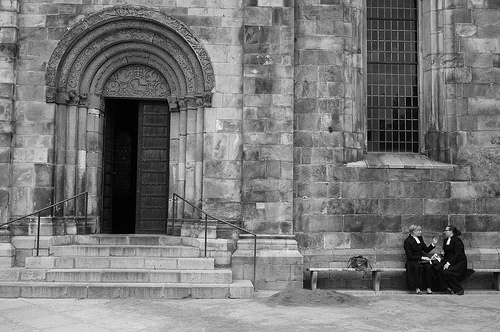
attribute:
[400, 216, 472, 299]
people — seated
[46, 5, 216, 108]
archway — STONE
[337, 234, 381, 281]
bird — SMALL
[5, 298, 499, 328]
road — CONCRETE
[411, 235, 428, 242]
collar — white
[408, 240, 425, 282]
dress — long, black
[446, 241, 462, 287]
dress — long, black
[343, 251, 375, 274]
purse — black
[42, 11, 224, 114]
arch way — large, curved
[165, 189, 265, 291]
railing — black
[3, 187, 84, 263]
railing — black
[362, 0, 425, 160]
window — GLASS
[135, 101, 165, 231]
door — open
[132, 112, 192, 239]
door — closed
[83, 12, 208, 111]
archway — carved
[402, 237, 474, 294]
costumes — black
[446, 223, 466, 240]
hair — black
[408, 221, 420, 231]
hair cut — short, blond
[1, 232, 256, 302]
steps — large, stone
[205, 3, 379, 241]
wall — white 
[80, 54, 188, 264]
door — OPEN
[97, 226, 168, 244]
step — at door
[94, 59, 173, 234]
door — dome shaped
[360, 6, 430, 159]
window — glass